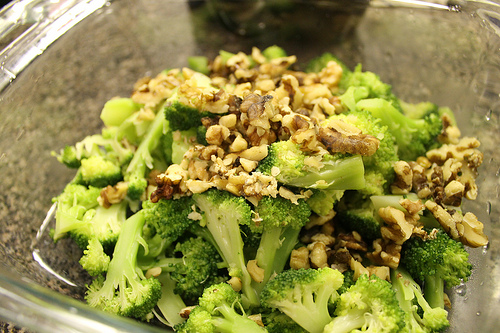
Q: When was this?
A: Daytime.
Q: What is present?
A: Food.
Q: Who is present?
A: Nobody.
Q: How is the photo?
A: Clear.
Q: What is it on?
A: A table.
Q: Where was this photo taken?
A: At a table.